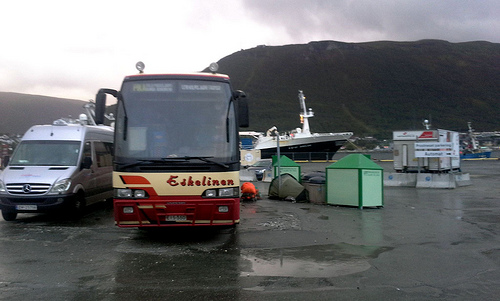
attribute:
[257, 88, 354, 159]
boat — black and white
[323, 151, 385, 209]
tent — green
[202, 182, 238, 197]
headlight — white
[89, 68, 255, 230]
bus — red and tan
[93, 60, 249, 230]
bus — red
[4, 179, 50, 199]
grille — chrome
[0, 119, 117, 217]
van — grey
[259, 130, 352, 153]
boat — blue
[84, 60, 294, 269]
bus — tan, red 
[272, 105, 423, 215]
tent — green 